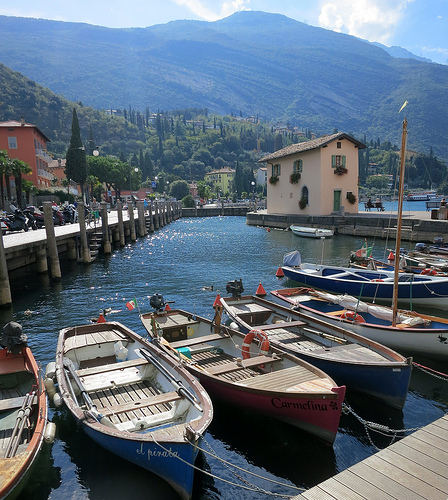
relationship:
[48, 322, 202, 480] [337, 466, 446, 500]
boat at dock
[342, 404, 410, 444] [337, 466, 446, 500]
ropes are on dock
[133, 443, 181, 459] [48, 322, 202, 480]
writing on boat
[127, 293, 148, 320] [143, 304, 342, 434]
flag on boat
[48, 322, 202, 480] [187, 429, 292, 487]
boat has rope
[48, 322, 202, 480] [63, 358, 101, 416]
boat has some oar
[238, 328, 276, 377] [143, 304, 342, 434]
life preserver in boat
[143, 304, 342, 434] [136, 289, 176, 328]
boat has a motor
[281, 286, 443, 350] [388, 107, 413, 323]
boat has a mast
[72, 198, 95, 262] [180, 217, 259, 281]
pilings are in water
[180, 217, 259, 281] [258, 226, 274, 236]
water has a buoy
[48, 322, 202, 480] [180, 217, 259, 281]
boat in water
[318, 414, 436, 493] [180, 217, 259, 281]
deck in water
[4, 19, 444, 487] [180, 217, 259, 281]
island in water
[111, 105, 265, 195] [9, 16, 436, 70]
trees are in distant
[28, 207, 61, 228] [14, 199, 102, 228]
bike in a group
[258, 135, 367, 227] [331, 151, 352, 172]
building has a window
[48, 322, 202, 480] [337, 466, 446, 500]
boat at a dock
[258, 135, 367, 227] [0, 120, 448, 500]
building in dock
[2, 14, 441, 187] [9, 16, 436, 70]
mountain in background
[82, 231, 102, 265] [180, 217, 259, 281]
stairs go to water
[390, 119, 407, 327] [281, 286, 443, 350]
mast in boat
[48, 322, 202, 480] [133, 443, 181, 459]
boat has a name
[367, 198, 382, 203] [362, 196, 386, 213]
people are on bench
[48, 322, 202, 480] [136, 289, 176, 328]
boat has a motor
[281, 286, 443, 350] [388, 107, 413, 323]
sailboat has a mast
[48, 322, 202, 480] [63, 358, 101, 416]
boat has an oar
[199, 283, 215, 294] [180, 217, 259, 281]
duck in water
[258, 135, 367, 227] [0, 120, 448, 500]
house in dock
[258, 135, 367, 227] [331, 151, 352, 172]
house has a window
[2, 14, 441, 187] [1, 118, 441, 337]
mountain behind town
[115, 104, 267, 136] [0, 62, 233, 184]
home on a slope